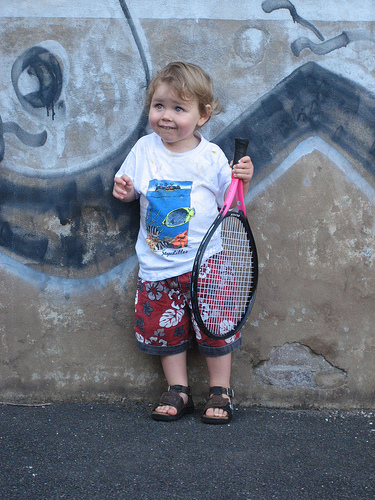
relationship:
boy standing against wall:
[109, 60, 255, 427] [0, 3, 363, 417]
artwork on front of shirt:
[144, 178, 192, 250] [113, 129, 231, 282]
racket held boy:
[196, 107, 271, 356] [109, 60, 255, 427]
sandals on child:
[148, 382, 240, 425] [101, 58, 263, 430]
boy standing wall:
[109, 60, 255, 427] [0, 3, 363, 417]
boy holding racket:
[109, 60, 255, 427] [189, 135, 258, 342]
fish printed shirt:
[143, 182, 195, 258] [125, 138, 226, 274]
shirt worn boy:
[113, 129, 231, 282] [109, 60, 255, 427]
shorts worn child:
[126, 260, 269, 370] [120, 62, 245, 387]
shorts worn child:
[132, 251, 242, 357] [119, 65, 255, 331]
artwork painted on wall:
[144, 178, 194, 258] [17, 66, 355, 380]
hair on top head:
[137, 61, 217, 121] [143, 58, 219, 148]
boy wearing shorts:
[109, 60, 255, 427] [132, 255, 247, 361]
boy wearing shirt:
[109, 60, 255, 427] [114, 130, 253, 284]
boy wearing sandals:
[109, 60, 255, 427] [202, 385, 237, 420]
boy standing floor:
[109, 60, 255, 427] [3, 408, 370, 498]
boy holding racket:
[107, 60, 261, 422] [187, 130, 262, 340]